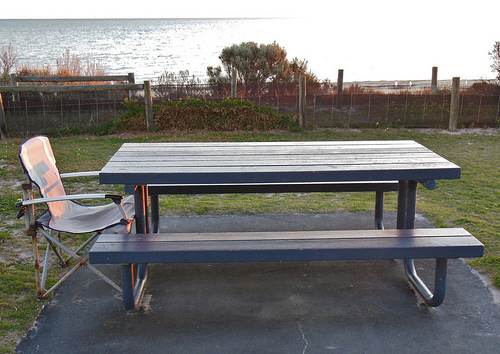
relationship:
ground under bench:
[62, 215, 497, 309] [74, 134, 488, 319]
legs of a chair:
[28, 229, 131, 303] [14, 134, 143, 310]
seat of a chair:
[46, 194, 137, 234] [10, 132, 141, 306]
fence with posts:
[7, 82, 495, 138] [0, 67, 500, 136]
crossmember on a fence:
[6, 69, 136, 84] [7, 82, 495, 138]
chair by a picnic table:
[15, 129, 150, 302] [87, 140, 485, 314]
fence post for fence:
[141, 77, 156, 132] [0, 98, 138, 128]